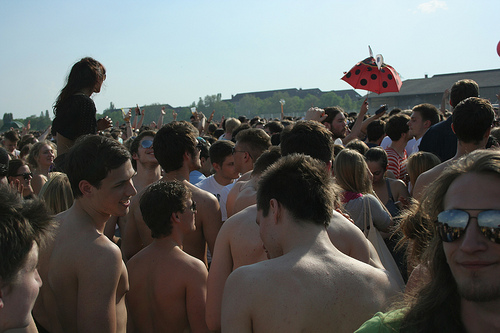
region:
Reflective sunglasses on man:
[431, 199, 498, 250]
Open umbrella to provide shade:
[337, 55, 404, 99]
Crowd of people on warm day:
[0, 110, 495, 325]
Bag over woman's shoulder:
[355, 192, 407, 300]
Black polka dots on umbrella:
[338, 55, 405, 95]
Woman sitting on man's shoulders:
[44, 53, 120, 185]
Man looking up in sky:
[127, 126, 168, 171]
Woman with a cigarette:
[392, 151, 442, 217]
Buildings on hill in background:
[212, 64, 497, 121]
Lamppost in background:
[274, 96, 290, 119]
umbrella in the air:
[338, 39, 406, 111]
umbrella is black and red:
[331, 43, 408, 108]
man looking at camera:
[316, 136, 498, 331]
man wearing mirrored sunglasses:
[426, 196, 499, 243]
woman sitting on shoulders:
[38, 46, 120, 161]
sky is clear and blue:
[1, 1, 499, 113]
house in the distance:
[365, 58, 499, 115]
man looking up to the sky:
[98, 124, 179, 263]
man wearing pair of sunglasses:
[134, 134, 159, 151]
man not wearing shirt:
[203, 151, 410, 331]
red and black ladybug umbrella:
[333, 39, 420, 108]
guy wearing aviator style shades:
[419, 157, 498, 305]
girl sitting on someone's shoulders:
[43, 39, 119, 174]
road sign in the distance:
[273, 93, 288, 117]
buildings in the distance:
[206, 80, 320, 117]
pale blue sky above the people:
[139, 25, 302, 75]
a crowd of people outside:
[140, 119, 397, 296]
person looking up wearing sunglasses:
[130, 128, 159, 174]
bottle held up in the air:
[133, 102, 145, 120]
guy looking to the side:
[63, 145, 151, 260]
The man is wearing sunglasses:
[435, 210, 499, 241]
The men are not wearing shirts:
[29, 138, 393, 331]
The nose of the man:
[461, 221, 484, 251]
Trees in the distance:
[197, 93, 357, 113]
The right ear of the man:
[171, 205, 182, 222]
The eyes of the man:
[112, 173, 135, 188]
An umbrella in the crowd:
[341, 60, 402, 104]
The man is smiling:
[358, 158, 498, 332]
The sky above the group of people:
[2, 1, 494, 111]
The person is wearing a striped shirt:
[387, 148, 408, 173]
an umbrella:
[343, 58, 402, 93]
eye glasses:
[184, 200, 199, 210]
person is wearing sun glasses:
[433, 209, 498, 236]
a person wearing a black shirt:
[58, 99, 90, 128]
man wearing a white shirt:
[204, 178, 224, 195]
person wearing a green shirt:
[366, 311, 410, 330]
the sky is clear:
[145, 19, 315, 74]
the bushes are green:
[233, 97, 268, 114]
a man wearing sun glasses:
[138, 135, 154, 148]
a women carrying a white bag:
[368, 215, 391, 242]